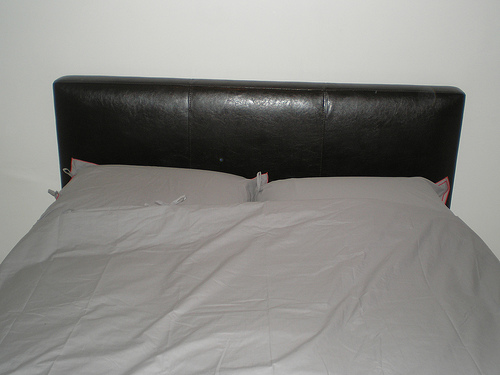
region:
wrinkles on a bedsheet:
[78, 225, 132, 303]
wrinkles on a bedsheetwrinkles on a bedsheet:
[175, 232, 240, 292]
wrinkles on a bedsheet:
[172, 271, 219, 331]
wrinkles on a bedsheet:
[97, 320, 162, 373]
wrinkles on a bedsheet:
[210, 338, 245, 373]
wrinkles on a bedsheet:
[309, 276, 365, 344]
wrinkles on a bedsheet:
[347, 232, 403, 316]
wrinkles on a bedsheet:
[297, 239, 347, 308]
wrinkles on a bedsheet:
[392, 212, 452, 284]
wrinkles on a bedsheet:
[423, 280, 487, 358]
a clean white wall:
[134, 9, 221, 67]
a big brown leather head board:
[62, 67, 452, 185]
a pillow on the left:
[56, 145, 233, 213]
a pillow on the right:
[259, 152, 456, 234]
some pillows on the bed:
[74, 139, 460, 236]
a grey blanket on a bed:
[29, 203, 494, 372]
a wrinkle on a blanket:
[167, 269, 227, 309]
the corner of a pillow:
[56, 149, 93, 182]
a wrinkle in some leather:
[174, 84, 204, 126]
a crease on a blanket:
[390, 253, 450, 304]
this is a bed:
[2, 49, 494, 371]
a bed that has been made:
[2, 48, 499, 362]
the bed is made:
[2, 64, 495, 374]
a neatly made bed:
[4, 51, 498, 372]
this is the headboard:
[40, 60, 490, 219]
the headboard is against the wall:
[28, 42, 480, 212]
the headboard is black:
[21, 45, 486, 221]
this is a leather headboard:
[28, 63, 485, 241]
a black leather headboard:
[22, 53, 493, 240]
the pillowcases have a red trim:
[48, 143, 488, 248]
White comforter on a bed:
[1, 192, 498, 373]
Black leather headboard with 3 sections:
[51, 73, 466, 209]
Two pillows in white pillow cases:
[47, 155, 452, 211]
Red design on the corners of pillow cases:
[66, 155, 453, 203]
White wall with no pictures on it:
[1, 2, 498, 263]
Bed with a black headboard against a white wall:
[1, 72, 499, 372]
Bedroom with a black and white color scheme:
[3, 2, 498, 374]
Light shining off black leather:
[218, 91, 313, 114]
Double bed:
[0, 74, 498, 374]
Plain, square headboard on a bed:
[52, 74, 466, 206]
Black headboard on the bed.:
[45, 70, 462, 190]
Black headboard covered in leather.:
[45, 66, 464, 192]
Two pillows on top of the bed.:
[50, 151, 453, 223]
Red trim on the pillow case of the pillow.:
[62, 152, 103, 172]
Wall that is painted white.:
[10, 5, 492, 63]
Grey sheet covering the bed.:
[20, 201, 496, 371]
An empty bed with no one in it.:
[9, 67, 499, 356]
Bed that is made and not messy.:
[7, 58, 497, 369]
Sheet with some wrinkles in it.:
[47, 203, 396, 361]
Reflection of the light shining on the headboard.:
[184, 77, 334, 122]